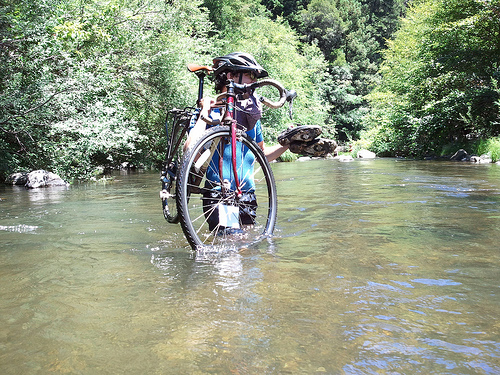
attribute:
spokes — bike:
[192, 137, 273, 252]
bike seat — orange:
[182, 63, 214, 73]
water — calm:
[1, 155, 498, 372]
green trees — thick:
[331, 17, 461, 147]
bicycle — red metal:
[220, 97, 245, 196]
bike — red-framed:
[124, 52, 293, 262]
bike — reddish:
[161, 53, 288, 270]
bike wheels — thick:
[173, 140, 270, 255]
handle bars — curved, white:
[208, 56, 296, 111]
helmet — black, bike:
[206, 50, 273, 77]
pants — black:
[204, 183, 256, 234]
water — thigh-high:
[281, 172, 362, 264]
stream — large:
[0, 157, 498, 373]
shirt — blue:
[212, 118, 266, 186]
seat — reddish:
[184, 60, 211, 76]